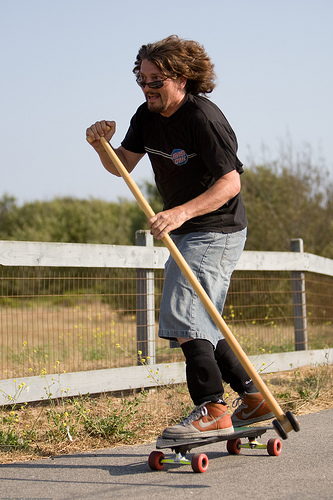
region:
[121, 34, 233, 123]
a head with long hair.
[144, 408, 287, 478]
a skateboard with four wheels.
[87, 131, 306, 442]
a long wooden mallet.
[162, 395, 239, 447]
a pair of orange shoes.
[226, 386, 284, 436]
an orange right shoe.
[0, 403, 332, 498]
a paved curvy road.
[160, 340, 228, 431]
ankle pads.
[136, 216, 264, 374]
blue jean shorts.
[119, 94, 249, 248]
a black t shirt.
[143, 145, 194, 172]
a logo printed on a shirt.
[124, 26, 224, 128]
man with long hair blowing in the wind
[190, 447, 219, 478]
red skate board wheel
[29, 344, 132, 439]
weeds growing along the side of a road with yellow flowers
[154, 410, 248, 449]
old orange nike shoes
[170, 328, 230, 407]
black knee pads worn around the ankles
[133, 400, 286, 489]
old wooden skate board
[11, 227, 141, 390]
wood and metal fence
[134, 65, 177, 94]
black sun glasses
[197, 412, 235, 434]
white nike swish symbol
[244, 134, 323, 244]
shrubs growing the background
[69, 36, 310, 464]
man riding a skateboard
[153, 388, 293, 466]
the shoes are orange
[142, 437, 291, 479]
the wheels are red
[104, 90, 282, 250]
man wearing a shirt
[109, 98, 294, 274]
the shirt is black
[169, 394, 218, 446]
the shoelace is white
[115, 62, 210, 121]
man is wearing a sunglasses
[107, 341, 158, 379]
the flowers are yellow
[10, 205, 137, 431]
the fence is gray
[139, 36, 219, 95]
the hair is brown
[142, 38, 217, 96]
mans hair blowing backwards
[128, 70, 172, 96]
sunglasses on mans face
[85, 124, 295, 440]
pole used to push skateboard on road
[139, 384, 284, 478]
skateboard stood on by man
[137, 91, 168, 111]
goatee on the mans face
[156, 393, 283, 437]
sneakers on top of the skateboard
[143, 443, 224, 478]
front skateboard wheels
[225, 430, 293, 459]
back skateboard wheels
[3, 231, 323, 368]
a fence along the side of the road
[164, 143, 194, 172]
an insignia on the mans short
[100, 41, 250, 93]
mans hair blowing in the wind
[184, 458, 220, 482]
red skateboard wheel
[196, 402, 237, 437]
red sneakers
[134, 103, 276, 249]
the mans is wearing a black shirt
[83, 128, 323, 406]
the man holding the a stick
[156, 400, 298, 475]
a skateboard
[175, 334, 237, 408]
black pads on the mans legs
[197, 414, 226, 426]
white logo on the shoes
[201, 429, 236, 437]
white soles on the shoes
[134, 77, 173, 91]
glasses on the mans face